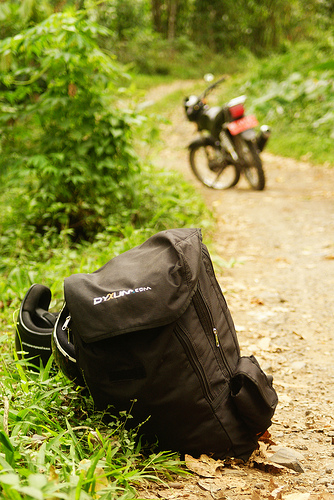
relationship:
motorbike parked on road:
[184, 78, 270, 190] [121, 78, 332, 496]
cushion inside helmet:
[27, 287, 58, 326] [13, 276, 63, 362]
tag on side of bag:
[213, 327, 220, 348] [63, 227, 278, 462]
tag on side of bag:
[213, 327, 220, 348] [35, 229, 262, 466]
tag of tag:
[212, 328, 219, 347] [213, 327, 220, 348]